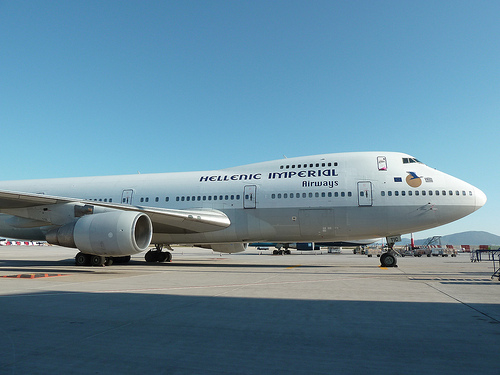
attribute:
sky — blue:
[1, 2, 497, 239]